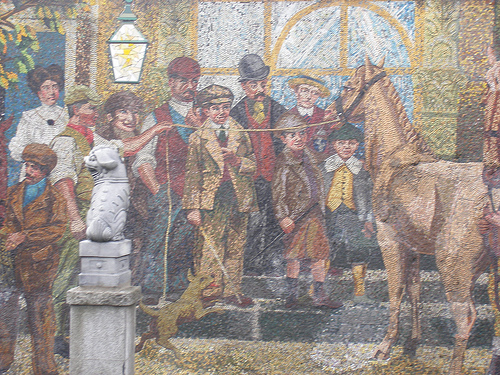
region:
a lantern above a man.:
[100, 12, 157, 88]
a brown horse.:
[318, 54, 498, 359]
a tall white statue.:
[55, 128, 149, 374]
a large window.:
[180, 0, 428, 154]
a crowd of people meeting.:
[4, 42, 496, 374]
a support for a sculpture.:
[56, 268, 152, 373]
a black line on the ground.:
[164, 281, 497, 349]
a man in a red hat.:
[157, 53, 211, 113]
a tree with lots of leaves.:
[0, 0, 103, 123]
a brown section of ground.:
[136, 330, 498, 372]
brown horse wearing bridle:
[318, 54, 498, 374]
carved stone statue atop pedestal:
[53, 134, 150, 371]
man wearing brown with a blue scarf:
[3, 143, 65, 372]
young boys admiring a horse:
[266, 120, 381, 295]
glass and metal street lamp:
[102, 5, 154, 87]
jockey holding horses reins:
[55, 82, 175, 344]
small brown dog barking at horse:
[138, 257, 236, 359]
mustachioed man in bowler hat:
[228, 51, 288, 182]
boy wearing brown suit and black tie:
[186, 80, 258, 307]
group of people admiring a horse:
[10, 59, 392, 356]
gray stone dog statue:
[77, 142, 136, 258]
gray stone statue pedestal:
[44, 230, 151, 372]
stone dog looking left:
[75, 140, 135, 245]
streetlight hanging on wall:
[100, 2, 158, 90]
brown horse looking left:
[317, 50, 491, 369]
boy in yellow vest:
[313, 120, 377, 307]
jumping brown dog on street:
[133, 267, 250, 366]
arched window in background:
[270, 2, 439, 103]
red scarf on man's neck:
[59, 113, 101, 148]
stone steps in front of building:
[148, 231, 496, 361]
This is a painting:
[15, 21, 482, 366]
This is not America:
[11, 52, 455, 312]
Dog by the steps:
[125, 249, 241, 366]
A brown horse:
[309, 47, 475, 362]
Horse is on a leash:
[155, 80, 387, 212]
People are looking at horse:
[3, 48, 413, 330]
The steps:
[210, 190, 452, 356]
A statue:
[56, 118, 161, 340]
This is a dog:
[47, 110, 181, 270]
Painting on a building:
[180, 10, 432, 156]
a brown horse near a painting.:
[320, 55, 497, 372]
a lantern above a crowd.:
[82, 17, 162, 107]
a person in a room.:
[55, 78, 175, 275]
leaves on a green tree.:
[0, 0, 88, 172]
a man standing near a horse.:
[314, 115, 389, 310]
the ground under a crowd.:
[125, 341, 497, 373]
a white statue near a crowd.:
[62, 123, 132, 374]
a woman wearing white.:
[5, 62, 87, 222]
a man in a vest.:
[116, 53, 201, 305]